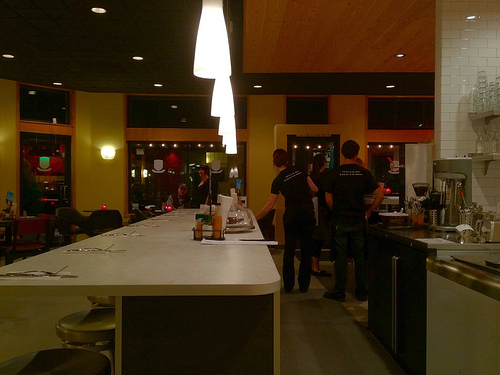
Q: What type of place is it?
A: It is a restaurant.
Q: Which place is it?
A: It is a restaurant.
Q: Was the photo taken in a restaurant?
A: Yes, it was taken in a restaurant.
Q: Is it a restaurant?
A: Yes, it is a restaurant.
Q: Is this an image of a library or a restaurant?
A: It is showing a restaurant.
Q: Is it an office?
A: No, it is a restaurant.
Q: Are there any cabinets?
A: Yes, there is a cabinet.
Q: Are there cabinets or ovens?
A: Yes, there is a cabinet.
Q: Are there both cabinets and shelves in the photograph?
A: Yes, there are both a cabinet and a shelf.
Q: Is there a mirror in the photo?
A: No, there are no mirrors.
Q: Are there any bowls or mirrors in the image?
A: No, there are no mirrors or bowls.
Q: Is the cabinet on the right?
A: Yes, the cabinet is on the right of the image.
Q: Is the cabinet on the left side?
A: No, the cabinet is on the right of the image.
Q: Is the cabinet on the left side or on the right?
A: The cabinet is on the right of the image.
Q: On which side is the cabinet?
A: The cabinet is on the right of the image.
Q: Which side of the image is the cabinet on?
A: The cabinet is on the right of the image.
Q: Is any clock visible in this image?
A: No, there are no clocks.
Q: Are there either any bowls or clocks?
A: No, there are no clocks or bowls.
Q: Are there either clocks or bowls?
A: No, there are no clocks or bowls.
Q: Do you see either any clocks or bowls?
A: No, there are no clocks or bowls.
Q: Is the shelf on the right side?
A: Yes, the shelf is on the right of the image.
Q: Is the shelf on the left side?
A: No, the shelf is on the right of the image.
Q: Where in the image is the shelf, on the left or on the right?
A: The shelf is on the right of the image.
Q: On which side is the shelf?
A: The shelf is on the right of the image.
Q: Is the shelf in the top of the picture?
A: Yes, the shelf is in the top of the image.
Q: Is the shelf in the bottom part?
A: No, the shelf is in the top of the image.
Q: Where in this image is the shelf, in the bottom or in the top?
A: The shelf is in the top of the image.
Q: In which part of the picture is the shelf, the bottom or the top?
A: The shelf is in the top of the image.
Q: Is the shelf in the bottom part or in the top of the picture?
A: The shelf is in the top of the image.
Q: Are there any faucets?
A: No, there are no faucets.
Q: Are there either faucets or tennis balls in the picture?
A: No, there are no faucets or tennis balls.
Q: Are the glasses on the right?
A: Yes, the glasses are on the right of the image.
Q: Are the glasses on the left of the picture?
A: No, the glasses are on the right of the image.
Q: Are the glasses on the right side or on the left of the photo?
A: The glasses are on the right of the image.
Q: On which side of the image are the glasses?
A: The glasses are on the right of the image.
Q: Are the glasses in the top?
A: Yes, the glasses are in the top of the image.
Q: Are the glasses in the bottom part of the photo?
A: No, the glasses are in the top of the image.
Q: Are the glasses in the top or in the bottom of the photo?
A: The glasses are in the top of the image.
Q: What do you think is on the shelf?
A: The glasses are on the shelf.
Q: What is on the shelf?
A: The glasses are on the shelf.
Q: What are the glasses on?
A: The glasses are on the shelf.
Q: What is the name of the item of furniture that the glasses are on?
A: The piece of furniture is a shelf.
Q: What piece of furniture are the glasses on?
A: The glasses are on the shelf.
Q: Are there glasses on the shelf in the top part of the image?
A: Yes, there are glasses on the shelf.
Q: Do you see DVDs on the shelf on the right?
A: No, there are glasses on the shelf.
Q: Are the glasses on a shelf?
A: Yes, the glasses are on a shelf.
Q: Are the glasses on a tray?
A: No, the glasses are on a shelf.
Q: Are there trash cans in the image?
A: No, there are no trash cans.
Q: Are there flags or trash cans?
A: No, there are no trash cans or flags.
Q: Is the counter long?
A: Yes, the counter is long.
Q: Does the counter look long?
A: Yes, the counter is long.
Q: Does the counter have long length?
A: Yes, the counter is long.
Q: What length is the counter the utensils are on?
A: The counter is long.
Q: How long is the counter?
A: The counter is long.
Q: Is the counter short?
A: No, the counter is long.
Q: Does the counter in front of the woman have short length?
A: No, the counter is long.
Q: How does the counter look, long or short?
A: The counter is long.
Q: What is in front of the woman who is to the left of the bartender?
A: The counter is in front of the woman.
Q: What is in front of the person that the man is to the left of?
A: The counter is in front of the woman.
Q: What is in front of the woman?
A: The counter is in front of the woman.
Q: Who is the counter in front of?
A: The counter is in front of the woman.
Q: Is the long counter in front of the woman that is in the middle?
A: Yes, the counter is in front of the woman.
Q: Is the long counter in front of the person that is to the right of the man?
A: Yes, the counter is in front of the woman.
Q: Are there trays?
A: No, there are no trays.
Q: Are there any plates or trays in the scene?
A: No, there are no trays or plates.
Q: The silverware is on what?
A: The silverware is on the counter.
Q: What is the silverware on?
A: The silverware is on the counter.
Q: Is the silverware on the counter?
A: Yes, the silverware is on the counter.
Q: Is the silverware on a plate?
A: No, the silverware is on the counter.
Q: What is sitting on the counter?
A: The silverware is sitting on the counter.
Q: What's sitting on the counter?
A: The silverware is sitting on the counter.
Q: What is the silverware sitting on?
A: The silverware is sitting on the counter.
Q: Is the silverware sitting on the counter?
A: Yes, the silverware is sitting on the counter.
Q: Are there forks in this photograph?
A: Yes, there is a fork.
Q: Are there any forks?
A: Yes, there is a fork.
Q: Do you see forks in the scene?
A: Yes, there is a fork.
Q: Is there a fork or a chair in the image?
A: Yes, there is a fork.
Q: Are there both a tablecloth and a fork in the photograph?
A: No, there is a fork but no tablecloths.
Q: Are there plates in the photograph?
A: No, there are no plates.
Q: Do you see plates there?
A: No, there are no plates.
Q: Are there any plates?
A: No, there are no plates.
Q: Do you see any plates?
A: No, there are no plates.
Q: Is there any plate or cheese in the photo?
A: No, there are no plates or cheese.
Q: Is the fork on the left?
A: Yes, the fork is on the left of the image.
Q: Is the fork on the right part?
A: No, the fork is on the left of the image.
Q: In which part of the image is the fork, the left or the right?
A: The fork is on the left of the image.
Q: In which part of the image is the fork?
A: The fork is on the left of the image.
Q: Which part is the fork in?
A: The fork is on the left of the image.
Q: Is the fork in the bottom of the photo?
A: Yes, the fork is in the bottom of the image.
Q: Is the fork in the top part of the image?
A: No, the fork is in the bottom of the image.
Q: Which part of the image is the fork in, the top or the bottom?
A: The fork is in the bottom of the image.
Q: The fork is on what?
A: The fork is on the counter.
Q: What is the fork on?
A: The fork is on the counter.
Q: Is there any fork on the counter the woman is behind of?
A: Yes, there is a fork on the counter.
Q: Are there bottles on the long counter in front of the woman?
A: No, there is a fork on the counter.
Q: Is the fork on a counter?
A: Yes, the fork is on a counter.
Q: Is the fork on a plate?
A: No, the fork is on a counter.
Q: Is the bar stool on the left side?
A: Yes, the bar stool is on the left of the image.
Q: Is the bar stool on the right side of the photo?
A: No, the bar stool is on the left of the image.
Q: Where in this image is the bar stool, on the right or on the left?
A: The bar stool is on the left of the image.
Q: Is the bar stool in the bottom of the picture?
A: Yes, the bar stool is in the bottom of the image.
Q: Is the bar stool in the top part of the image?
A: No, the bar stool is in the bottom of the image.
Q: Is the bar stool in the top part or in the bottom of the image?
A: The bar stool is in the bottom of the image.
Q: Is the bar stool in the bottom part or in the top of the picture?
A: The bar stool is in the bottom of the image.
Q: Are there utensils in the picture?
A: Yes, there are utensils.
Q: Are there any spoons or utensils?
A: Yes, there are utensils.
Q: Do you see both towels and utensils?
A: No, there are utensils but no towels.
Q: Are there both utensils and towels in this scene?
A: No, there are utensils but no towels.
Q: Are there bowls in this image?
A: No, there are no bowls.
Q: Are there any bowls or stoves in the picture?
A: No, there are no bowls or stoves.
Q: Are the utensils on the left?
A: Yes, the utensils are on the left of the image.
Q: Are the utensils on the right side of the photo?
A: No, the utensils are on the left of the image.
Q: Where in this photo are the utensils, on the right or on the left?
A: The utensils are on the left of the image.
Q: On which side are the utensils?
A: The utensils are on the left of the image.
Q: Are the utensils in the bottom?
A: Yes, the utensils are in the bottom of the image.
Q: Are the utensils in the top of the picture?
A: No, the utensils are in the bottom of the image.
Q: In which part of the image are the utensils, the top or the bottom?
A: The utensils are in the bottom of the image.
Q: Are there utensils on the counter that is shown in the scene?
A: Yes, there are utensils on the counter.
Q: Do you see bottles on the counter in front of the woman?
A: No, there are utensils on the counter.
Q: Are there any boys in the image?
A: No, there are no boys.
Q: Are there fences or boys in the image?
A: No, there are no boys or fences.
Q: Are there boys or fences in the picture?
A: No, there are no boys or fences.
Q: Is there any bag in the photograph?
A: No, there are no bags.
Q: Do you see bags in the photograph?
A: No, there are no bags.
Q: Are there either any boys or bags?
A: No, there are no bags or boys.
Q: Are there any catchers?
A: No, there are no catchers.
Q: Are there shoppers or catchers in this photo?
A: No, there are no catchers or shoppers.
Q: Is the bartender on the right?
A: Yes, the bartender is on the right of the image.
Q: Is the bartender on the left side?
A: No, the bartender is on the right of the image.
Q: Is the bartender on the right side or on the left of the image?
A: The bartender is on the right of the image.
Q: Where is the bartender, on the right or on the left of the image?
A: The bartender is on the right of the image.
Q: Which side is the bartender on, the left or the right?
A: The bartender is on the right of the image.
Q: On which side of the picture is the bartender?
A: The bartender is on the right of the image.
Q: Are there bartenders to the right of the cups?
A: Yes, there is a bartender to the right of the cups.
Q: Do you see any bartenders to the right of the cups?
A: Yes, there is a bartender to the right of the cups.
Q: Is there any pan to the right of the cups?
A: No, there is a bartender to the right of the cups.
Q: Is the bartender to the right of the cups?
A: Yes, the bartender is to the right of the cups.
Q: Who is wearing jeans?
A: The bartender is wearing jeans.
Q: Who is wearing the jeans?
A: The bartender is wearing jeans.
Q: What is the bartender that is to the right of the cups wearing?
A: The bartender is wearing jeans.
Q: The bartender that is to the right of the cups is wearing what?
A: The bartender is wearing jeans.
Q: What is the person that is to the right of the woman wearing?
A: The bartender is wearing jeans.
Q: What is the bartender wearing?
A: The bartender is wearing jeans.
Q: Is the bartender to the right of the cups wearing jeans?
A: Yes, the bartender is wearing jeans.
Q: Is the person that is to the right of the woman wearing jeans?
A: Yes, the bartender is wearing jeans.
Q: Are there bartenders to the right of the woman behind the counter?
A: Yes, there is a bartender to the right of the woman.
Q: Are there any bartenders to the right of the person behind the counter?
A: Yes, there is a bartender to the right of the woman.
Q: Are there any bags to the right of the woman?
A: No, there is a bartender to the right of the woman.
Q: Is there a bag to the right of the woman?
A: No, there is a bartender to the right of the woman.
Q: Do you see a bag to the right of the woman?
A: No, there is a bartender to the right of the woman.